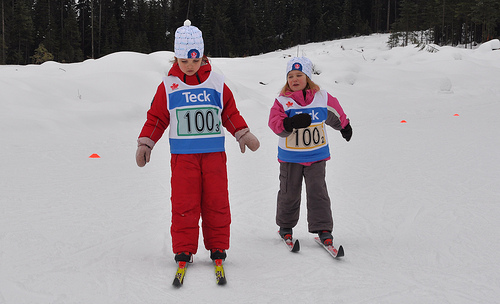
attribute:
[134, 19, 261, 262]
child — young, skiing, girl, on left, learning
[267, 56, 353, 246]
child — young, skiing, girl, on right, learning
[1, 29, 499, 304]
ground — snowy, white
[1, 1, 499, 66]
trees — green, long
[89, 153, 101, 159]
safety cone — orange, trail marker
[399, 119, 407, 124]
safety cone — orange, trail marker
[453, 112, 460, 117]
safety cone — orange, trail marker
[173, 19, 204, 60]
hat — white, knit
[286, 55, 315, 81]
hat — white, knit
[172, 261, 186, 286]
ski — small, yellow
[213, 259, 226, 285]
ski — small, yellow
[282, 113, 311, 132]
mitten — black, empty, warm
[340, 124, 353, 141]
mitten — black, empty, warm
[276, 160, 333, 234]
ski pants — grey, brown, gray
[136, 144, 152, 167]
mitten — beige, empty, warm, brown, dark brown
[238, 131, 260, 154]
mitten — beige, empty, warm, brown, dark brown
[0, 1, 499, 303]
landscape — winter, snowy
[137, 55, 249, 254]
ski suit — red, orange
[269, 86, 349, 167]
coat — pink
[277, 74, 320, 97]
hair — long